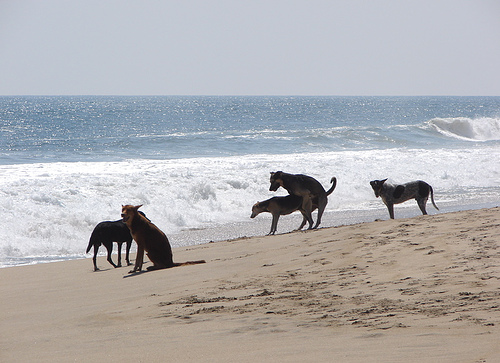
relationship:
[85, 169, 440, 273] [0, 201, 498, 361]
brown dogs are in beach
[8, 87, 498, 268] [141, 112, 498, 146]
water has waves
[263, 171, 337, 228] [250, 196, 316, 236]
dog humping dog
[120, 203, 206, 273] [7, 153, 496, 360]
brown dogs sitting on beach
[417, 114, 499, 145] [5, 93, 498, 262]
wave breaking into ocean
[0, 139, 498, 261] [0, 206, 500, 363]
wave crashing into beach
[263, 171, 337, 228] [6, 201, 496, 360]
dog are standing on sand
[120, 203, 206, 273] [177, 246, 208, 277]
brown dogs has tail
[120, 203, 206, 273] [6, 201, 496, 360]
brown dogs on sand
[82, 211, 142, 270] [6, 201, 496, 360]
dog on sand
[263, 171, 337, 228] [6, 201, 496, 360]
dog on sand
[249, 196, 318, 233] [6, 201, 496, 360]
dog on sand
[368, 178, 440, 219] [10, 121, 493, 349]
dog on beach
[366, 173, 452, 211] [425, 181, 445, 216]
dog has tail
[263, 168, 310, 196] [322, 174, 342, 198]
dog has tail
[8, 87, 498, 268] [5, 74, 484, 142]
water in distance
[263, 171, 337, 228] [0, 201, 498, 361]
dog on beach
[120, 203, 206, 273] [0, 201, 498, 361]
brown dogs on beach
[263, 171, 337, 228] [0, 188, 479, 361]
dog on beach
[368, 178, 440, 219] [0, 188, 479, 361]
dog on beach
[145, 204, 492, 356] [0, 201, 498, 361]
footprints on beach